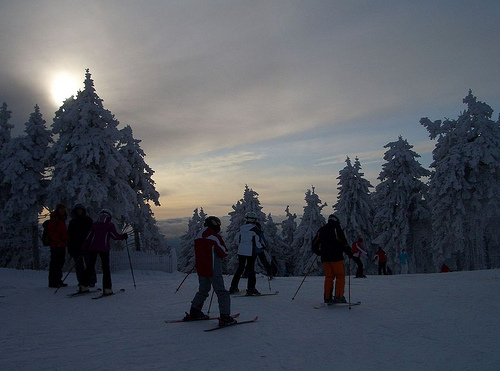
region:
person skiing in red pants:
[298, 211, 365, 318]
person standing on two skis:
[172, 210, 257, 340]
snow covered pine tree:
[421, 86, 498, 269]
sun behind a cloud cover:
[33, 61, 92, 111]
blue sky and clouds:
[184, 95, 333, 184]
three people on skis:
[161, 192, 368, 337]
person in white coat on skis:
[224, 203, 282, 301]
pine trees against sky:
[373, 85, 499, 234]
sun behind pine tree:
[35, 51, 138, 203]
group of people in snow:
[170, 195, 368, 341]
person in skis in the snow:
[287, 208, 377, 313]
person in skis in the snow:
[161, 209, 261, 339]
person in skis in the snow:
[219, 207, 284, 301]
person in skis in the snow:
[47, 207, 141, 304]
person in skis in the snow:
[348, 231, 377, 286]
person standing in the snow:
[35, 198, 75, 293]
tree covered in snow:
[285, 182, 330, 275]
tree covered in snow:
[330, 149, 375, 275]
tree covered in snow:
[367, 131, 430, 273]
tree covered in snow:
[46, 58, 141, 225]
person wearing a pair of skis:
[288, 209, 372, 319]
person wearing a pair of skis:
[348, 232, 373, 282]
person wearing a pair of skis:
[225, 207, 285, 299]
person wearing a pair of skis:
[157, 207, 262, 333]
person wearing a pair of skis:
[49, 203, 142, 305]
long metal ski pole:
[288, 247, 324, 302]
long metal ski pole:
[344, 250, 356, 314]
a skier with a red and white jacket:
[165, 211, 263, 335]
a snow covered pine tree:
[418, 86, 496, 265]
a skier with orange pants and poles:
[292, 208, 365, 313]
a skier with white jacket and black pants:
[224, 210, 282, 299]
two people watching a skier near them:
[37, 200, 139, 300]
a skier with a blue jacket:
[395, 244, 414, 271]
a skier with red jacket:
[370, 243, 392, 275]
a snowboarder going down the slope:
[347, 235, 371, 277]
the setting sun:
[41, 68, 84, 110]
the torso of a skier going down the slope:
[437, 260, 454, 272]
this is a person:
[285, 216, 370, 324]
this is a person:
[161, 213, 249, 330]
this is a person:
[231, 215, 289, 315]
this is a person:
[85, 206, 133, 302]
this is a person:
[65, 198, 101, 284]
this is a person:
[32, 195, 68, 288]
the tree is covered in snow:
[52, 61, 137, 257]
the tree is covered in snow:
[173, 196, 218, 301]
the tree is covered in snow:
[225, 183, 273, 293]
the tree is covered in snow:
[291, 180, 343, 310]